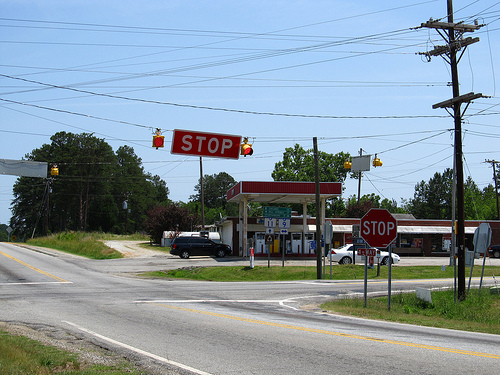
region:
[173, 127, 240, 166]
Stop sign hanging from wire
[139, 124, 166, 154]
Red light is turned on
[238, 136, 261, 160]
Red light hanging over street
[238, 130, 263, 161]
Red light is turned on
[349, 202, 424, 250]
Stop sign at intersection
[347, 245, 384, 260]
Intersection is 4 way stop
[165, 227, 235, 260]
Suv parked at gas station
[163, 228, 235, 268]
Parked SUV is black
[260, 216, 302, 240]
Route signs posted at intersection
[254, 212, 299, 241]
Route signs at intersection are white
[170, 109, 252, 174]
red and white stop sign over street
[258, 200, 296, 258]
directional signs on metal poles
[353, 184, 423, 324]
red stopsign on metal pole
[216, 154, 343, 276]
owning over gas pump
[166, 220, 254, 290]
black SUV parked at gas station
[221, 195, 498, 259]
red brick building holding gas station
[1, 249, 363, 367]
side roads off main road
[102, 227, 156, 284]
dirt and gravel drive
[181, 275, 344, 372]
yellow and white painted lines on roadway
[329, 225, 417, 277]
white ar parked in parking lot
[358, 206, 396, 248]
An octagonal red and white stop sign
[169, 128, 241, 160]
A rectangular red and white stop sign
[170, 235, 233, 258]
A black SUV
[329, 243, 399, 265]
A white car in front of a gas station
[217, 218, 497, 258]
A gas stationg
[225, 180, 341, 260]
A red and white gas station awning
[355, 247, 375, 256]
A sign indicating a four way stop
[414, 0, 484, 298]
A telephone pole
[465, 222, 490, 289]
The back side of a stop sign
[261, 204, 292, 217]
A group of green road signs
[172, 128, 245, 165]
a rectangular stop sign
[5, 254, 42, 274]
yellow lines in the street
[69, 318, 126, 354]
white line on the stree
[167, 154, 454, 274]
a gas station at an intersection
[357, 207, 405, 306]
a stop sign on the corner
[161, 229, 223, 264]
a black van parked nearby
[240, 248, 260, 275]
a white pole with orange tip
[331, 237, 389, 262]
a white car driving past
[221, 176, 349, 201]
red and white shelter over the gas island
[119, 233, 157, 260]
a dirt road next to the gas station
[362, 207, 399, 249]
a red and white stop sign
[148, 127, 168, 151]
a yellow street light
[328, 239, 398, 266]
a white car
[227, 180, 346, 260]
part of a gas station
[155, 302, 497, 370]
a yellow street marking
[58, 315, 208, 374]
a white street marking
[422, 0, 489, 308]
a tall light pole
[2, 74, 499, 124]
an electrical wire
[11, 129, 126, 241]
a tall green tree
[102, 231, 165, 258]
a small country road